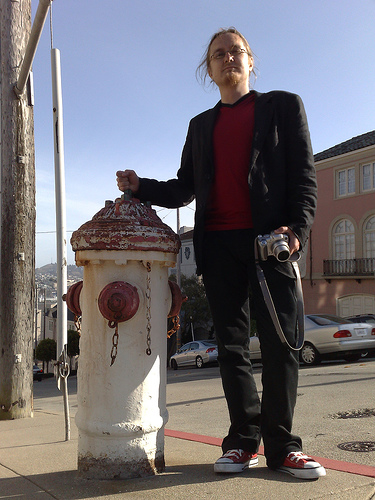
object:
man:
[110, 26, 332, 492]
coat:
[135, 89, 322, 282]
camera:
[251, 229, 304, 265]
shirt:
[215, 90, 245, 229]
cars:
[167, 336, 220, 372]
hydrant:
[63, 184, 186, 490]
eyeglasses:
[205, 46, 251, 61]